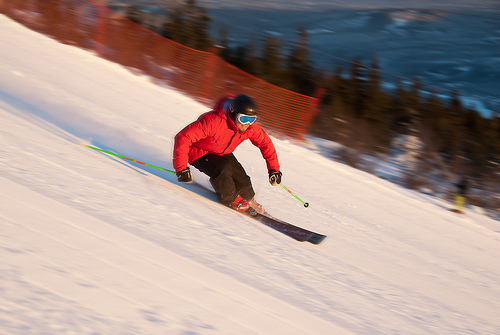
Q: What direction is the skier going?
A: Downhill.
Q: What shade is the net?
A: Orange.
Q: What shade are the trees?
A: Green.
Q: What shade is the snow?
A: White.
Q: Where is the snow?
A: Mountain.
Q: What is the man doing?
A: Skiing.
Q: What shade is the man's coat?
A: Red.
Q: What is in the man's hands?
A: Ski sticks.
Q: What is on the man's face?
A: Gargles.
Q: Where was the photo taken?
A: At a ski slope.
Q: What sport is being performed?
A: Skiing.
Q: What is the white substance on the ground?
A: Snow.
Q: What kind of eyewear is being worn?
A: Goggles.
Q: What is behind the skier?
A: Orange netting.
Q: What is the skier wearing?
A: Red coat.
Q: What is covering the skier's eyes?
A: Goggles.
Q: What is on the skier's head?
A: A helmet.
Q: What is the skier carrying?
A: Green poles.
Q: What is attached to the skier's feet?
A: Skis.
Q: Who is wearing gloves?
A: The skier.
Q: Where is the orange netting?
A: Behind the skier.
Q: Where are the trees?
A: Behind the net.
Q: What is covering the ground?
A: Snow.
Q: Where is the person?
A: On the mountain.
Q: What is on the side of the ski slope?
A: A safety wall.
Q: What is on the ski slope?
A: Snow.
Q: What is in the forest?
A: Trees.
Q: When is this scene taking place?
A: Daytime.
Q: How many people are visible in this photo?
A: One.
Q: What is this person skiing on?
A: Hill.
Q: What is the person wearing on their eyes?
A: Goggles.